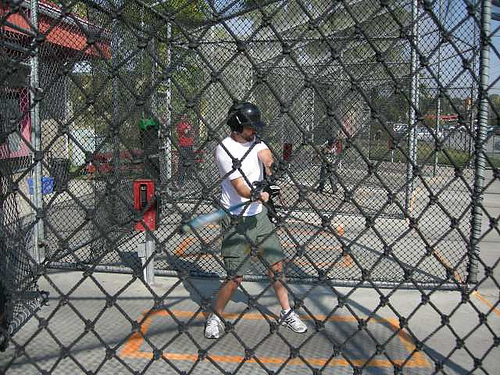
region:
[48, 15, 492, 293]
black fence around the batting cage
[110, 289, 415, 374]
orange painted batter's box on the pavement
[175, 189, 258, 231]
person holding a blue bat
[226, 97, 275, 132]
person is wearing a helmet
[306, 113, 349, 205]
person several cages down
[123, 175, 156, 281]
red box on a post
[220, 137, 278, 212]
person is wearing a white t-shirt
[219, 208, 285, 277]
person is wearing cargo shorts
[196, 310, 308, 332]
white tennis shoes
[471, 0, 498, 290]
tall metal pole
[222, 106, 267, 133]
The black helmet the batter has on.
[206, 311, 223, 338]
The batter's left sneaker.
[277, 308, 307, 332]
The batter's right sneaker.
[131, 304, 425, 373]
The orange square the batter is standing in.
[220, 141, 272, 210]
The white shirt the batter is wearing.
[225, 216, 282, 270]
The shorts the batter is wearing.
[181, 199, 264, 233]
The bat in the batter's hand.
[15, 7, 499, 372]
The chained link fence.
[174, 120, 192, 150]
The man in the red shirt.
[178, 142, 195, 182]
The pants the man in the red shirt is wearing.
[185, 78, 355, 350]
this is a man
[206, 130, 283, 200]
man wearing a white shirt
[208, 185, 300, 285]
man wearing pair of shorts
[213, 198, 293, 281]
man wearing green shorts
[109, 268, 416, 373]
yellow box on ground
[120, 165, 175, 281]
red box on side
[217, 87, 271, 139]
man wearing baseball helmet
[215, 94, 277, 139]
baseball helmet is black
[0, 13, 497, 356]
metal fence is black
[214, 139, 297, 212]
man with arms extended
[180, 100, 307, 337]
a man using a batting cage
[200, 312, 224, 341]
a man's white tennis shoe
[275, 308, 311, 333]
a man's white tennis shoe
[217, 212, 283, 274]
a man's green shorts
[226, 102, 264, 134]
black helmet on a man's head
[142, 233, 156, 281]
a metal pole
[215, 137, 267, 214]
a man's white t shirt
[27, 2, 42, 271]
a metal post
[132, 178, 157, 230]
a red metal box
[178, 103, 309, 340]
Man in a batting cage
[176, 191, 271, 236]
A bat being swung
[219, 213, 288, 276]
Dark gray shorts on a man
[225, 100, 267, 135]
Black helmet on a man's head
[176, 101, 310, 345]
Man swinging a bat at a ball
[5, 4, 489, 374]
A black netting around the cage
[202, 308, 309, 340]
A pair of white shoes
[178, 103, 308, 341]
A man standing behind a net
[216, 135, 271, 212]
White shirt on a man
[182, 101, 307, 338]
Man in a white shirt swings a bat